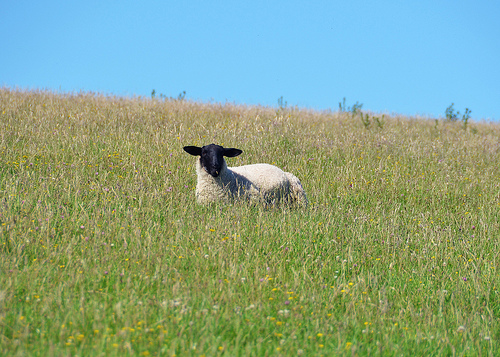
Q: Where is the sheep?
A: In a field.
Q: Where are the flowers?
A: In the grass.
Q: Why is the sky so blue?
A: No clouds.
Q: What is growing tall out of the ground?
A: Grass.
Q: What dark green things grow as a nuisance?
A: Weeds.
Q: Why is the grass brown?
A: Dying.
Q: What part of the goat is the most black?
A: Face.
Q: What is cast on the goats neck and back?
A: Shadow.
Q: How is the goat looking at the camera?
A: With eyes.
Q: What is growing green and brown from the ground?
A: Grass.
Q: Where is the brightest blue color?
A: In the sky.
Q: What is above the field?
A: Sky.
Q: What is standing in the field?
A: Sheep.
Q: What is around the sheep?
A: Grass.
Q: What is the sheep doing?
A: Standing.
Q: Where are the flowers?
A: In grass.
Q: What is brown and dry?
A: Grass.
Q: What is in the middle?
A: Sheep.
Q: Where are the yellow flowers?
A: In the field.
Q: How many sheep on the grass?
A: One.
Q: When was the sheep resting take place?
A: Daytime.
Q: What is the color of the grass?
A: Green.